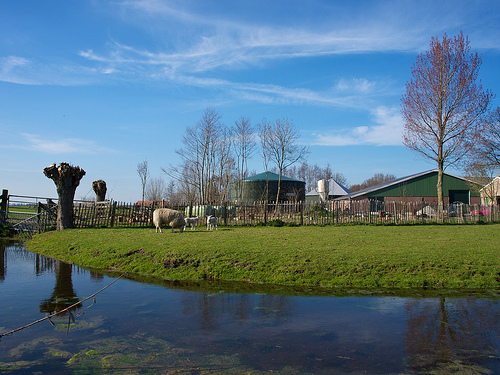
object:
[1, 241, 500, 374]
water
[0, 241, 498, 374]
pond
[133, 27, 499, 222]
trees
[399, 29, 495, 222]
tree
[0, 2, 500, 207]
clouds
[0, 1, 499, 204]
sky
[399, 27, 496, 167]
leaves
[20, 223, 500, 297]
grass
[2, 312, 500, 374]
moss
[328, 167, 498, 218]
building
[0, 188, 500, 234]
fence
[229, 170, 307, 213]
silo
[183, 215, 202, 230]
lamb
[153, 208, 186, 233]
sheep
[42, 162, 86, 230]
cut-off tree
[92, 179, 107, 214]
tree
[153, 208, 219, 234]
animals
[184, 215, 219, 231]
baby animals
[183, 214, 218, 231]
lambs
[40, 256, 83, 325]
reflection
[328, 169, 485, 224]
house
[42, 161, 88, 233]
tree trunk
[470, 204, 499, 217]
car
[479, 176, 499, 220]
barn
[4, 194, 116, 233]
gate